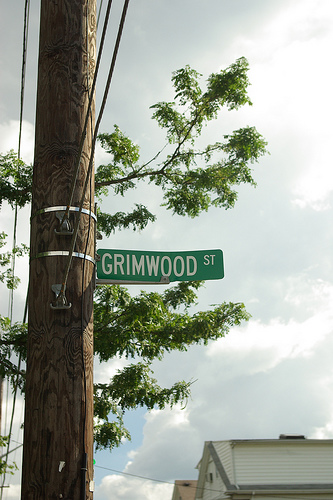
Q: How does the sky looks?
A: Cloudy.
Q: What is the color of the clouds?
A: White.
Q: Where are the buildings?
A: To the right.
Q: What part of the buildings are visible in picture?
A: Roof.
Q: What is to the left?
A: Pole.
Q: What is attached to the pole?
A: Street sign.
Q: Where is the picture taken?
A: Grimwood street.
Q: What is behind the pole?
A: A tree.